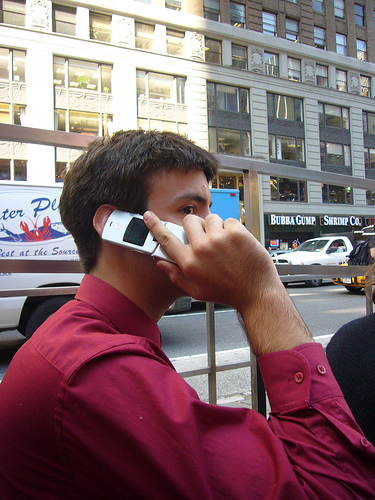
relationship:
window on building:
[262, 50, 280, 75] [1, 1, 374, 255]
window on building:
[232, 3, 247, 27] [1, 1, 374, 255]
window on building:
[334, 69, 349, 93] [1, 1, 374, 255]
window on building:
[336, 34, 350, 58] [1, 1, 374, 255]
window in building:
[334, 69, 349, 93] [1, 1, 374, 255]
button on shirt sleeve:
[317, 361, 329, 375] [56, 336, 374, 497]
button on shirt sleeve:
[291, 371, 307, 385] [56, 336, 374, 497]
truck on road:
[0, 175, 93, 344] [1, 259, 372, 437]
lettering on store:
[266, 212, 362, 229] [266, 214, 367, 275]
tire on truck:
[20, 292, 80, 342] [0, 175, 93, 344]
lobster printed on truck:
[14, 212, 63, 245] [0, 175, 93, 344]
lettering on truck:
[0, 245, 75, 257] [0, 175, 93, 344]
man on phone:
[0, 123, 369, 491] [98, 205, 207, 265]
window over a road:
[334, 69, 349, 93] [1, 259, 372, 437]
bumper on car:
[330, 273, 366, 285] [328, 242, 373, 300]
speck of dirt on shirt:
[137, 413, 145, 419] [0, 261, 357, 492]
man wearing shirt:
[0, 261, 357, 492] [0, 261, 357, 492]